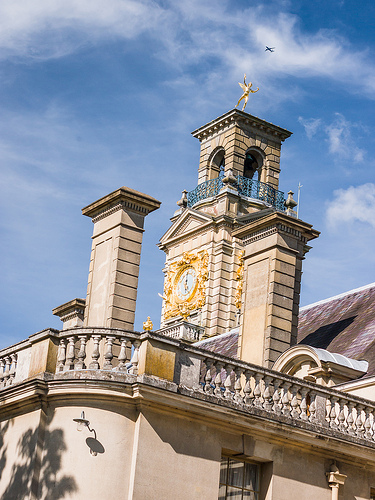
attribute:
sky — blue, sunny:
[1, 0, 373, 353]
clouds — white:
[0, 0, 373, 240]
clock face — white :
[165, 265, 203, 308]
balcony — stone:
[3, 323, 371, 463]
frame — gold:
[163, 252, 212, 316]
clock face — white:
[172, 266, 199, 304]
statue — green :
[232, 70, 260, 111]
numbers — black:
[176, 268, 195, 299]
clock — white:
[176, 267, 196, 299]